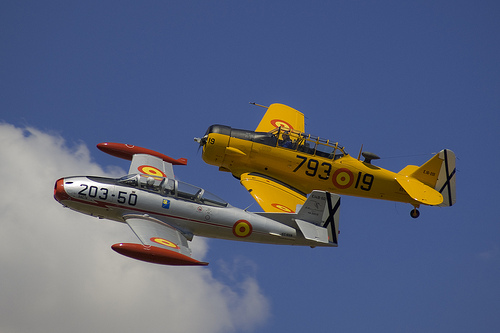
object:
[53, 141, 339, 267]
airplane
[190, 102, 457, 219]
airplane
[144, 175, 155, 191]
pilot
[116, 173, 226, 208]
cockpit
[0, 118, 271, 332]
cloud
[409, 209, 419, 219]
landing gear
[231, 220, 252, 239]
circle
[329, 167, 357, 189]
circle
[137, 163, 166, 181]
circle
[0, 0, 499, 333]
sky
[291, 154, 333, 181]
793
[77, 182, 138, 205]
203-50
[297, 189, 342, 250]
tail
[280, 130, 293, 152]
pilot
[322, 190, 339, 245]
spot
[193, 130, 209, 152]
propeller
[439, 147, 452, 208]
spot